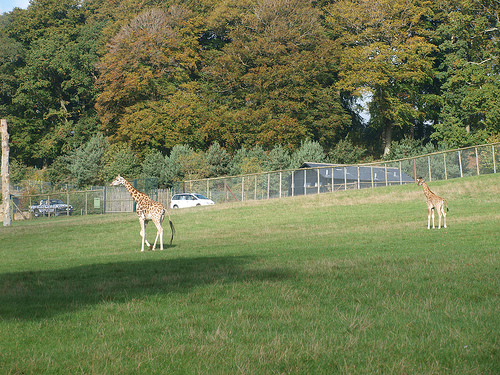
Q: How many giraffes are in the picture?
A: Two.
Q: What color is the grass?
A: Green.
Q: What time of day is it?
A: Day time.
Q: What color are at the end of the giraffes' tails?
A: Black.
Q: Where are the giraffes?
A: In a field.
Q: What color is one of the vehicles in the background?
A: White.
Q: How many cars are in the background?
A: Two.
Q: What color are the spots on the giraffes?
A: Brown.